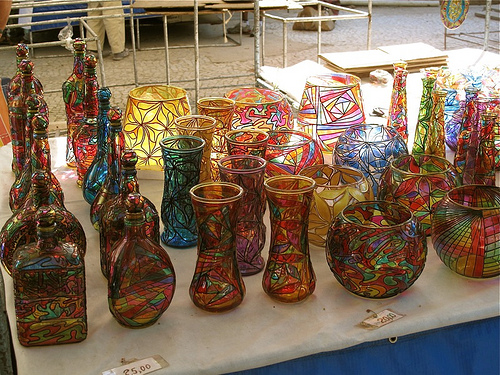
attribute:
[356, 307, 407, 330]
tag — price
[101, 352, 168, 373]
tag — price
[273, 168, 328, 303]
vase — glass, blue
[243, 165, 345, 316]
vase — blue, glass, round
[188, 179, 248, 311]
vase — glass, purple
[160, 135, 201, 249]
vase — glass, purple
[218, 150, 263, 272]
vase — glass, purple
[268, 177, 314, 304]
vase — glass, purple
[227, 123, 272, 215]
vase — glass, purple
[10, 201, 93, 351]
vase — multi-colored, glass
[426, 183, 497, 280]
vase — round, multi colored, glass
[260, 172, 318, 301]
vase — multi colored, glass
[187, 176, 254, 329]
glass vase — multi colored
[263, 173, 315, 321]
glass vase — multi colored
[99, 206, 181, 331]
glass vase — multi colored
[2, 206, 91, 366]
glass vase — multi colored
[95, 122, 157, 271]
glass vase — multi colored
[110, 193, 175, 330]
glass vase — multi colored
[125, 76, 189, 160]
glass vase — circular, yellow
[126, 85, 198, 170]
vase — glass, yellow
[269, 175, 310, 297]
vase — glass, yellow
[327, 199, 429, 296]
vase — glass, yellow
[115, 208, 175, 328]
vase — glass, yellow